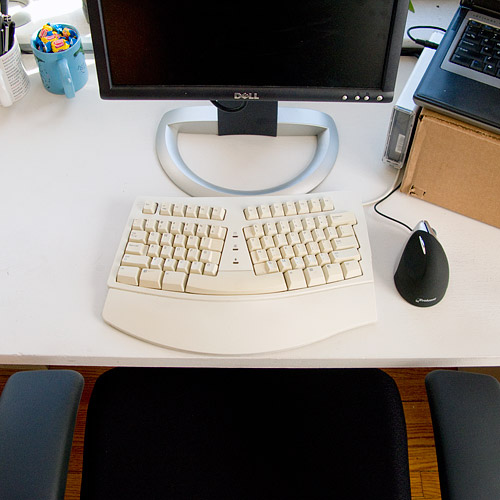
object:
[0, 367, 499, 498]
chair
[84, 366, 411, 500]
seat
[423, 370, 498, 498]
arm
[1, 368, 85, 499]
arm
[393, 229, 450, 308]
mouse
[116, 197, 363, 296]
keyboard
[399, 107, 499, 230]
box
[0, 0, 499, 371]
table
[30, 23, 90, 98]
cup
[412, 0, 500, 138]
laptop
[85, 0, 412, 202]
computer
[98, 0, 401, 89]
screen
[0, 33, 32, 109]
cup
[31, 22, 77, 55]
gum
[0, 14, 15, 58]
markers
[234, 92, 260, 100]
dell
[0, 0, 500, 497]
picture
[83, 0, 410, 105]
monitor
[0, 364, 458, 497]
floor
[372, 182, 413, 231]
cord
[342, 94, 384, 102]
control buttons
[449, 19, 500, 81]
keyboard